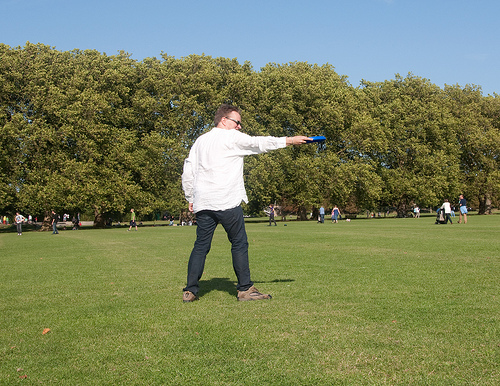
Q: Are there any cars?
A: No, there are no cars.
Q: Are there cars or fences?
A: No, there are no cars or fences.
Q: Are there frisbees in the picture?
A: Yes, there is a frisbee.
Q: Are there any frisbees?
A: Yes, there is a frisbee.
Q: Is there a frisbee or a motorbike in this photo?
A: Yes, there is a frisbee.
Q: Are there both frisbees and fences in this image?
A: No, there is a frisbee but no fences.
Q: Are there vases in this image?
A: No, there are no vases.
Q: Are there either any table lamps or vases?
A: No, there are no vases or table lamps.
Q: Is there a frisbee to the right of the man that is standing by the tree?
A: Yes, there is a frisbee to the right of the man.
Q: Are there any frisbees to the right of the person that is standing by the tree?
A: Yes, there is a frisbee to the right of the man.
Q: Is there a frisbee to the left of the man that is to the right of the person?
A: No, the frisbee is to the right of the man.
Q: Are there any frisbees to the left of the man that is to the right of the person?
A: No, the frisbee is to the right of the man.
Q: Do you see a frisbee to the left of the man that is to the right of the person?
A: No, the frisbee is to the right of the man.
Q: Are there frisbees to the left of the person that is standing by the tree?
A: No, the frisbee is to the right of the man.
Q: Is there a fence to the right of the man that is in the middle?
A: No, there is a frisbee to the right of the man.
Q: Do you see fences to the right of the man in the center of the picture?
A: No, there is a frisbee to the right of the man.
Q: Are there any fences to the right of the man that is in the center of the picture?
A: No, there is a frisbee to the right of the man.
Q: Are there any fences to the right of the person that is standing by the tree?
A: No, there is a frisbee to the right of the man.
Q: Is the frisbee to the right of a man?
A: Yes, the frisbee is to the right of a man.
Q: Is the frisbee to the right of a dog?
A: No, the frisbee is to the right of a man.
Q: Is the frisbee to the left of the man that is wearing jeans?
A: No, the frisbee is to the right of the man.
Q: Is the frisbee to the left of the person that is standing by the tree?
A: No, the frisbee is to the right of the man.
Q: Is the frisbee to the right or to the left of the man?
A: The frisbee is to the right of the man.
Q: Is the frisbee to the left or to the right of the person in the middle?
A: The frisbee is to the right of the man.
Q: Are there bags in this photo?
A: No, there are no bags.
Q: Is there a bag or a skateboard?
A: No, there are no bags or skateboards.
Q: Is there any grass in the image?
A: Yes, there is grass.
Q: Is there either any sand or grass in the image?
A: Yes, there is grass.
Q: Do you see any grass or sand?
A: Yes, there is grass.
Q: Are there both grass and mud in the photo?
A: No, there is grass but no mud.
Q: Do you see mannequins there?
A: No, there are no mannequins.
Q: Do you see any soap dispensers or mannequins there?
A: No, there are no mannequins or soap dispensers.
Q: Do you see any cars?
A: No, there are no cars.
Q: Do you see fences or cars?
A: No, there are no cars or fences.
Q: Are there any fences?
A: No, there are no fences.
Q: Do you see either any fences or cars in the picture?
A: No, there are no fences or cars.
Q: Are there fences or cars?
A: No, there are no fences or cars.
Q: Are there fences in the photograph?
A: No, there are no fences.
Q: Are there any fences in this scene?
A: No, there are no fences.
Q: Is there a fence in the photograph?
A: No, there are no fences.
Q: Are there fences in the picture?
A: No, there are no fences.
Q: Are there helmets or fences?
A: No, there are no fences or helmets.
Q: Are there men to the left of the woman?
A: Yes, there is a man to the left of the woman.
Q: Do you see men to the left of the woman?
A: Yes, there is a man to the left of the woman.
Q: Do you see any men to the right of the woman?
A: No, the man is to the left of the woman.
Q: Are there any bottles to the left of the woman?
A: No, there is a man to the left of the woman.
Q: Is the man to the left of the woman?
A: Yes, the man is to the left of the woman.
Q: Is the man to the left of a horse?
A: No, the man is to the left of the woman.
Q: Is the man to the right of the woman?
A: No, the man is to the left of the woman.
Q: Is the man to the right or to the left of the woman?
A: The man is to the left of the woman.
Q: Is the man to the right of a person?
A: Yes, the man is to the right of a person.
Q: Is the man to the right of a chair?
A: No, the man is to the right of a person.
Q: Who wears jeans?
A: The man wears jeans.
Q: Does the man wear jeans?
A: Yes, the man wears jeans.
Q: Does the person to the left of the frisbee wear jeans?
A: Yes, the man wears jeans.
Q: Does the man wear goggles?
A: No, the man wears jeans.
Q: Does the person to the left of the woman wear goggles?
A: No, the man wears jeans.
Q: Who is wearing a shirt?
A: The man is wearing a shirt.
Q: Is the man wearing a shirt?
A: Yes, the man is wearing a shirt.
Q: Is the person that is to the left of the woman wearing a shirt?
A: Yes, the man is wearing a shirt.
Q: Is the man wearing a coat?
A: No, the man is wearing a shirt.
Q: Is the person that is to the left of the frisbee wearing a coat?
A: No, the man is wearing a shirt.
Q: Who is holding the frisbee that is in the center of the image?
A: The man is holding the frisbee.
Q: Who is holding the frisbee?
A: The man is holding the frisbee.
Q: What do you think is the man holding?
A: The man is holding the frisbee.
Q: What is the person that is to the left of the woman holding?
A: The man is holding the frisbee.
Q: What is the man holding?
A: The man is holding the frisbee.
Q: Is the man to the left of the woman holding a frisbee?
A: Yes, the man is holding a frisbee.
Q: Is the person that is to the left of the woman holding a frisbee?
A: Yes, the man is holding a frisbee.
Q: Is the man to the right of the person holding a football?
A: No, the man is holding a frisbee.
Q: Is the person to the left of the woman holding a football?
A: No, the man is holding a frisbee.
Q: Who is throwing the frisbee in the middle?
A: The man is throwing the frisbee.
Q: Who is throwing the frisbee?
A: The man is throwing the frisbee.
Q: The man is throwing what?
A: The man is throwing the frisbee.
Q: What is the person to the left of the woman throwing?
A: The man is throwing the frisbee.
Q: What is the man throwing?
A: The man is throwing the frisbee.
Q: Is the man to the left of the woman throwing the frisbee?
A: Yes, the man is throwing the frisbee.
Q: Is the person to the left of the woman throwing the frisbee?
A: Yes, the man is throwing the frisbee.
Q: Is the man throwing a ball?
A: No, the man is throwing the frisbee.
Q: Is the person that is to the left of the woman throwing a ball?
A: No, the man is throwing the frisbee.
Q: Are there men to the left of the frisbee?
A: Yes, there is a man to the left of the frisbee.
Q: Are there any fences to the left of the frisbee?
A: No, there is a man to the left of the frisbee.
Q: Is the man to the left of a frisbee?
A: Yes, the man is to the left of a frisbee.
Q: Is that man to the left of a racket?
A: No, the man is to the left of a frisbee.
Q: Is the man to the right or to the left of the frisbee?
A: The man is to the left of the frisbee.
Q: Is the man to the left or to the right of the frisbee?
A: The man is to the left of the frisbee.